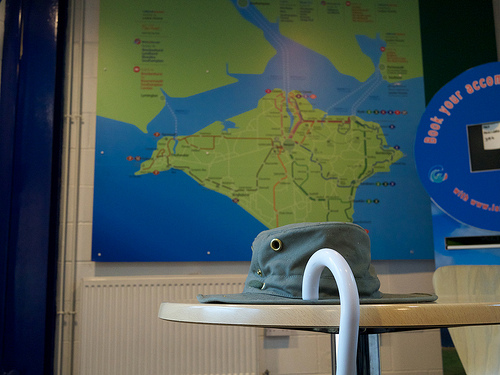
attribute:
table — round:
[157, 287, 481, 347]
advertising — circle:
[416, 63, 499, 233]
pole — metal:
[304, 251, 364, 323]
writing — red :
[428, 69, 472, 146]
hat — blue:
[196, 220, 440, 305]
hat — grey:
[190, 197, 450, 317]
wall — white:
[63, 2, 443, 374]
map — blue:
[92, 1, 438, 273]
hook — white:
[300, 245, 364, 373]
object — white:
[307, 261, 358, 372]